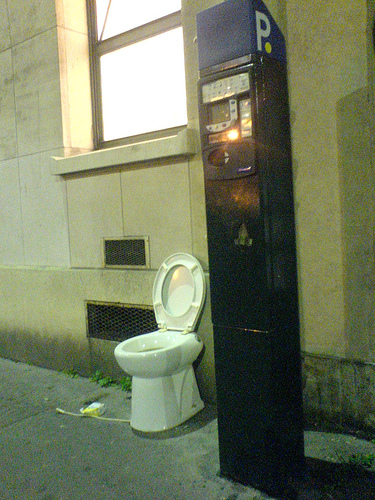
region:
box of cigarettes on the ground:
[78, 395, 114, 416]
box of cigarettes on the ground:
[48, 388, 128, 429]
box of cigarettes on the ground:
[71, 391, 109, 426]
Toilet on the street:
[73, 234, 214, 427]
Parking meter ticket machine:
[182, 29, 316, 197]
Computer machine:
[167, 27, 265, 182]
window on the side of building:
[62, 36, 189, 161]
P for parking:
[247, 8, 324, 105]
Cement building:
[37, 26, 337, 294]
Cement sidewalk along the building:
[35, 439, 147, 477]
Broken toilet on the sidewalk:
[90, 260, 218, 429]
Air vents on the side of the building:
[72, 211, 165, 271]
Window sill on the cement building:
[32, 117, 227, 235]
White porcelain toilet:
[118, 248, 204, 433]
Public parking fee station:
[192, 7, 311, 482]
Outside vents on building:
[72, 225, 150, 335]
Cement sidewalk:
[1, 401, 241, 493]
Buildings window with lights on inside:
[45, 0, 192, 182]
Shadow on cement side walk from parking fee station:
[205, 392, 358, 494]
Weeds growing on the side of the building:
[16, 346, 127, 391]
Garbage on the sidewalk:
[40, 378, 156, 448]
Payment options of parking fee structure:
[189, 69, 279, 185]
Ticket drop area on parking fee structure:
[217, 213, 271, 270]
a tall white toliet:
[112, 250, 207, 434]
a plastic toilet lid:
[151, 251, 206, 330]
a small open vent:
[101, 236, 150, 269]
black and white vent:
[80, 299, 164, 346]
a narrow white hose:
[51, 407, 131, 424]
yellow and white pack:
[81, 398, 107, 417]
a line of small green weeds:
[62, 365, 132, 392]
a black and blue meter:
[195, 0, 306, 499]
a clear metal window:
[86, 0, 192, 151]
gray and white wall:
[0, 2, 373, 437]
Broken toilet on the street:
[106, 231, 231, 470]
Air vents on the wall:
[66, 199, 201, 300]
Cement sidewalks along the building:
[28, 459, 147, 479]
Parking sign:
[208, 12, 318, 60]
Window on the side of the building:
[79, 31, 224, 184]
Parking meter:
[189, 32, 290, 185]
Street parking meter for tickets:
[151, 6, 318, 214]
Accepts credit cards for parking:
[202, 60, 270, 168]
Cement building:
[43, 118, 133, 227]